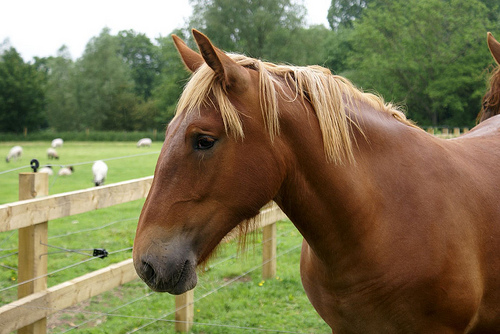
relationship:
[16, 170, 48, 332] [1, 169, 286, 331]
post on fence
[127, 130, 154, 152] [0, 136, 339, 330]
sheep in field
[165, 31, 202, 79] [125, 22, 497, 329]
ear of horse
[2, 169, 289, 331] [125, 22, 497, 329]
wooden fence to keep horse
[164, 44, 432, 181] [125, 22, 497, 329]
mane of horse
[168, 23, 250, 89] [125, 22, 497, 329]
ears of horse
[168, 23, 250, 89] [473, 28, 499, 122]
ears of horse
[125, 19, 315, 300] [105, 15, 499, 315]
head of horse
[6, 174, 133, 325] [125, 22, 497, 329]
wood fence behind horse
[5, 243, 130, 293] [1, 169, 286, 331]
wire along fence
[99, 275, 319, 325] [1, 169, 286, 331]
wire along fence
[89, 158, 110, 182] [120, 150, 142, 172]
sheep eating grass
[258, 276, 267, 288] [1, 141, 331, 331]
dandelions in grass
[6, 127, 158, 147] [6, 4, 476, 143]
green hedge in background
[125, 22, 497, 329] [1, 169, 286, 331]
horse by fence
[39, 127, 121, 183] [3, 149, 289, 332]
sheep on other side of fence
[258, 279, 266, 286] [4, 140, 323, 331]
dandelions on ground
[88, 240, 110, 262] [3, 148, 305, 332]
clip in wires